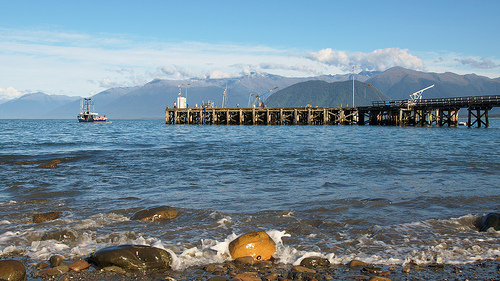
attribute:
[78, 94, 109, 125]
ship — here, coming, floating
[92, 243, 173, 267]
stone — here, large, dark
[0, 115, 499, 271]
water — cool, here, blue, wavy, choppy, coming, surrounding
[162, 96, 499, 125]
bridge — here, long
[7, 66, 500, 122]
mountains — here, background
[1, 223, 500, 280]
shore — rocky, here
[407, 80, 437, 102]
crane — sitting, tall, white